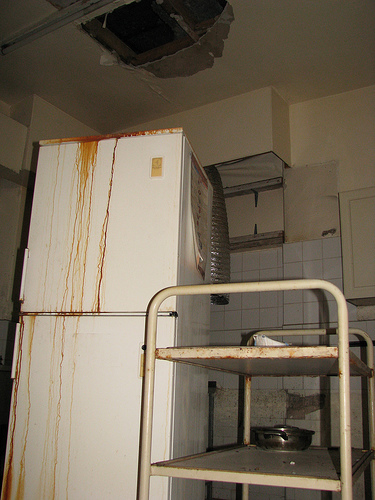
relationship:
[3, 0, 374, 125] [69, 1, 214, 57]
ceiling has hole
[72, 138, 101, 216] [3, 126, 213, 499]
rust down fridge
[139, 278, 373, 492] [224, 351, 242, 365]
shelves show rust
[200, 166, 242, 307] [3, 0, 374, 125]
ducting from ceiling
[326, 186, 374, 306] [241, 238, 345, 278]
cabinet on wall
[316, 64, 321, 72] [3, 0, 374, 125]
part of ceiling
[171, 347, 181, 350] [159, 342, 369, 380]
edge of shelf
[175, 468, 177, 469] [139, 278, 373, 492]
part of stand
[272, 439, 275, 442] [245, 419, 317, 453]
part of hotpot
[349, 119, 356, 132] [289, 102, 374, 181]
part of wall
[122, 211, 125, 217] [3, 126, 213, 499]
part of fridge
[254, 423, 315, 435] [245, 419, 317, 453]
lid of hotpot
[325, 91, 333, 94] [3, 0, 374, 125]
edge of ceiling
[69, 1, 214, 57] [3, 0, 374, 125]
hole in ceiling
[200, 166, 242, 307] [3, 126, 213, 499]
duct behind refrigerator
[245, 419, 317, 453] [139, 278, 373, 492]
pot on cart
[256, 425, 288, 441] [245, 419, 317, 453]
handle on pot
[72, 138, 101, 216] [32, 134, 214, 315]
rust on freezer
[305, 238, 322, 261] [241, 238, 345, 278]
tile on wall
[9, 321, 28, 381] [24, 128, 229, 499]
handle of refrigerator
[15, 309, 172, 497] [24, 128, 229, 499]
door of refrigerator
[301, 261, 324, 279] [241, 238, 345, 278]
tile on wall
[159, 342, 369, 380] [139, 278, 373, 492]
shelf of cart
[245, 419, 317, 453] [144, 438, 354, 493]
pan on shelf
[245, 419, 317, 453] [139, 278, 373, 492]
pan on cart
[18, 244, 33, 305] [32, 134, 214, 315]
handle of freezer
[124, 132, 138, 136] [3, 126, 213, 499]
edge of fridge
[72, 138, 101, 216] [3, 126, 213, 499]
rust on fridge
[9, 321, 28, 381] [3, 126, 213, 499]
handle on fridge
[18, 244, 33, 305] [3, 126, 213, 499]
handle on fridge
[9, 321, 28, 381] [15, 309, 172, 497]
handle of door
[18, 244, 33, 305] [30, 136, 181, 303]
handle of door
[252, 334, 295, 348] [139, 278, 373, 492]
paper on cart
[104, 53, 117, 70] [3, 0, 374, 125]
spot on ceiling